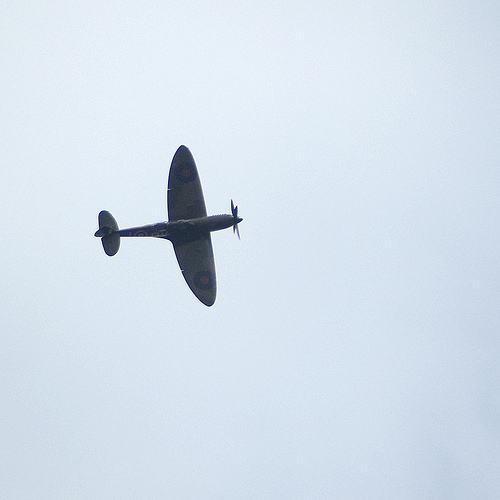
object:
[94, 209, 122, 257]
tail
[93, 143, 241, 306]
airplane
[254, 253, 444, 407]
clouds sky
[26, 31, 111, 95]
clouds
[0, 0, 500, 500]
sky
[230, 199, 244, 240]
propeller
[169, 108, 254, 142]
wall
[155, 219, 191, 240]
cockpit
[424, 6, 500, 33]
clouds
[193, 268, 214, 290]
insignia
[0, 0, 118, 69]
blue sky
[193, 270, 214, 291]
design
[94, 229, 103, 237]
rudder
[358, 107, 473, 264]
blue sky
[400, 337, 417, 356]
cloud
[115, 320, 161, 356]
cloud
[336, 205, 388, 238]
cloud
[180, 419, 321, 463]
cloud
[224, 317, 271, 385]
cloud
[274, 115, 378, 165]
cloud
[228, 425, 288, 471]
cloud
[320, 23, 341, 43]
cloud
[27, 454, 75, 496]
cloud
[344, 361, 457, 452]
cloud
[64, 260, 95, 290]
cloud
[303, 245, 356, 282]
cloud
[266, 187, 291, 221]
cloud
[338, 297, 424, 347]
cloud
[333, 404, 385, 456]
cloud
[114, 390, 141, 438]
cloud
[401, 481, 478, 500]
cloud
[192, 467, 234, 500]
cloud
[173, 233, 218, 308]
wing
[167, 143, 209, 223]
wing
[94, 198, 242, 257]
body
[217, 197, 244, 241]
front